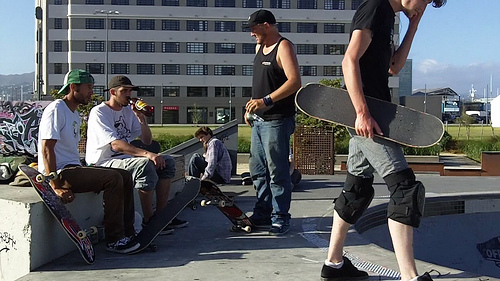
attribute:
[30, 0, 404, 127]
building — tall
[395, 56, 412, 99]
building — tall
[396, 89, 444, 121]
building — tall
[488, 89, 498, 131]
building — tall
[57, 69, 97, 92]
baseball cap — white, green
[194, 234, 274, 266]
ground — cement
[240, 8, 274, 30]
hat — black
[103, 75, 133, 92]
hat — black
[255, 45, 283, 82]
tank top — black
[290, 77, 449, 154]
skateboard — black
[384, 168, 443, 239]
kneepad — black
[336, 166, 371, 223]
kneepad — black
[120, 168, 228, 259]
skateboard — black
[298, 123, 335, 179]
waste bin — small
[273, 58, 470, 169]
skateboard — long, black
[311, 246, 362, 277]
shoes — black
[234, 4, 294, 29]
hat — black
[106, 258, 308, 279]
ground —  gray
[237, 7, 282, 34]
cap — black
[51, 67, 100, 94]
hat — green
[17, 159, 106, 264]
skateboard — colorful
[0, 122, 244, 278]
wall — white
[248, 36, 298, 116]
vest — black